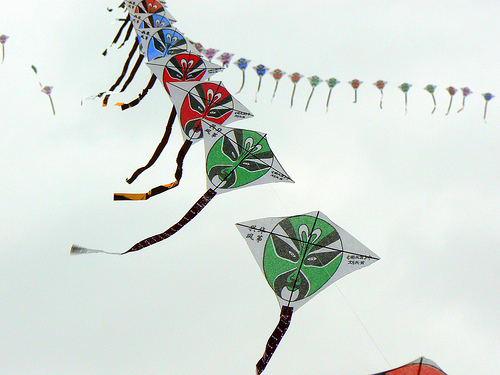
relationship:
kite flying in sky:
[221, 207, 381, 373] [0, 3, 497, 374]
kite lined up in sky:
[221, 207, 381, 373] [0, 3, 497, 374]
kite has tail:
[157, 78, 258, 149] [110, 140, 194, 206]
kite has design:
[221, 207, 381, 373] [262, 213, 345, 306]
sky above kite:
[0, 3, 497, 374] [157, 78, 258, 149]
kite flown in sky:
[157, 78, 258, 149] [0, 3, 497, 374]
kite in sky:
[157, 78, 258, 149] [0, 3, 497, 374]